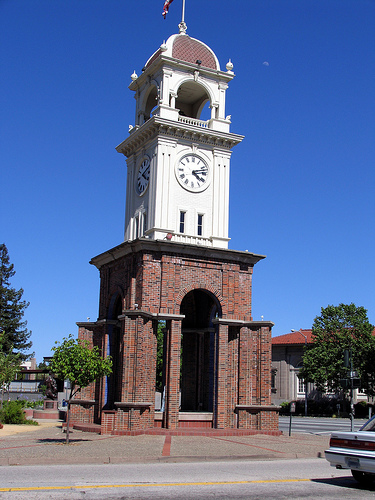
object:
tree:
[297, 302, 374, 429]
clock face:
[172, 151, 214, 193]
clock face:
[131, 153, 153, 202]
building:
[0, 355, 53, 404]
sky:
[0, 0, 374, 367]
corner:
[3, 404, 352, 467]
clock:
[171, 149, 217, 196]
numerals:
[179, 153, 204, 167]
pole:
[176, 1, 192, 22]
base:
[62, 250, 283, 433]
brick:
[204, 269, 238, 288]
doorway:
[172, 284, 230, 419]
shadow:
[37, 434, 93, 450]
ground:
[2, 418, 375, 454]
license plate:
[343, 457, 359, 467]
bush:
[48, 334, 113, 443]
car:
[324, 413, 375, 483]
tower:
[115, 29, 244, 248]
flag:
[160, 0, 176, 24]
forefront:
[23, 334, 312, 458]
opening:
[179, 288, 221, 414]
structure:
[67, 29, 284, 433]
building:
[63, 32, 281, 436]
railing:
[178, 117, 210, 126]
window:
[294, 371, 307, 398]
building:
[272, 320, 363, 413]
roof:
[272, 328, 360, 345]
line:
[4, 477, 350, 489]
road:
[1, 462, 361, 498]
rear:
[325, 431, 363, 469]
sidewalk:
[10, 429, 322, 454]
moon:
[260, 58, 270, 68]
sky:
[239, 8, 362, 252]